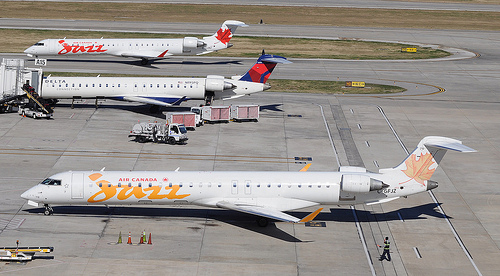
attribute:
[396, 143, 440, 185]
leaf — orange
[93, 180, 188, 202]
logo — orange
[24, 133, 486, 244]
plane — white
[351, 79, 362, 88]
sign — yellow, black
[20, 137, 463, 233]
aeroplane — white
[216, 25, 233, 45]
leaf — red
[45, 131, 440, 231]
airplane — large, white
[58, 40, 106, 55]
logo — red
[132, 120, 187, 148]
truck — white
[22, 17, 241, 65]
plane — white